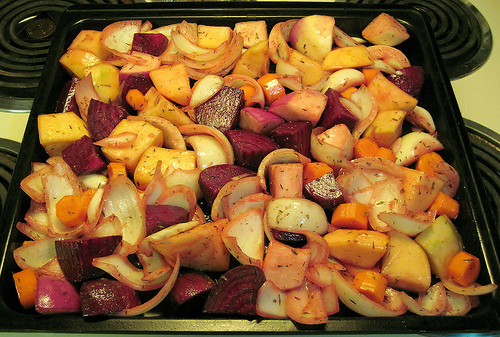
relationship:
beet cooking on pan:
[128, 27, 171, 60] [0, 0, 499, 336]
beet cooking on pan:
[83, 92, 133, 146] [0, 0, 499, 336]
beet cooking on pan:
[192, 81, 249, 141] [0, 0, 499, 336]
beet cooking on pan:
[195, 162, 264, 209] [0, 0, 499, 336]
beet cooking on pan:
[197, 260, 270, 322] [0, 0, 499, 336]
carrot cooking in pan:
[124, 87, 151, 115] [0, 0, 499, 336]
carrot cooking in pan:
[51, 192, 93, 231] [0, 0, 499, 336]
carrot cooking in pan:
[9, 265, 46, 312] [0, 0, 499, 336]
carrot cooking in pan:
[327, 200, 377, 235] [0, 0, 499, 336]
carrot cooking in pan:
[442, 247, 485, 290] [0, 0, 499, 336]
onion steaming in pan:
[260, 241, 313, 293] [0, 0, 499, 336]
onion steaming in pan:
[96, 17, 144, 64] [0, 0, 499, 336]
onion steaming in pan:
[88, 247, 181, 295] [0, 0, 499, 336]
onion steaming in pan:
[183, 70, 227, 118] [0, 0, 499, 336]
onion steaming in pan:
[167, 23, 234, 66] [0, 0, 499, 336]